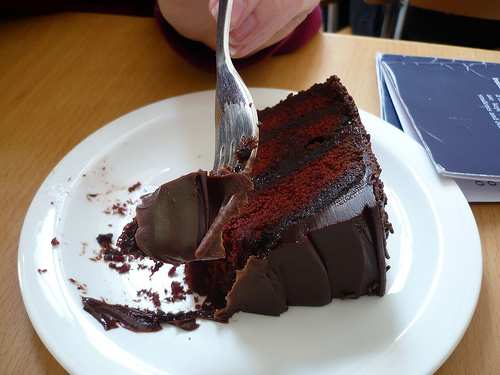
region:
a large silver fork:
[193, 3, 268, 190]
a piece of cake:
[104, 60, 416, 336]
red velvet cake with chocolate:
[93, 80, 410, 315]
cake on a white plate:
[18, 89, 487, 368]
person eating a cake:
[18, 5, 491, 372]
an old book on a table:
[366, 35, 498, 222]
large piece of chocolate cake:
[10, 7, 495, 373]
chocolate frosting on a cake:
[12, 60, 482, 365]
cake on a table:
[8, 9, 491, 370]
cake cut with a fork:
[21, 5, 494, 370]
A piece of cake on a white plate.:
[27, 81, 467, 373]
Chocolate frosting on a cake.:
[237, 209, 417, 341]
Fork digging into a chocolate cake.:
[166, 45, 303, 251]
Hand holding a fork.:
[136, 1, 286, 262]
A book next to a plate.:
[364, 46, 499, 213]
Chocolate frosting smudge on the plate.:
[65, 277, 208, 347]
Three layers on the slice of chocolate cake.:
[187, 73, 390, 313]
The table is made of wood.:
[13, 33, 498, 372]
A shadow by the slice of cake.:
[237, 278, 400, 360]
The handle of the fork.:
[198, 1, 245, 69]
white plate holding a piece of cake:
[35, 76, 442, 373]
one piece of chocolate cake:
[158, 78, 390, 304]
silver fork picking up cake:
[136, 66, 260, 273]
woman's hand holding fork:
[206, 2, 263, 172]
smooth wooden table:
[8, 20, 496, 360]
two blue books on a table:
[372, 49, 497, 209]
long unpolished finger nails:
[225, 11, 259, 63]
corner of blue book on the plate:
[404, 135, 475, 207]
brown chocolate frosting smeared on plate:
[74, 293, 197, 340]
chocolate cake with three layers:
[259, 75, 391, 299]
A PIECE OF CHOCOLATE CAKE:
[112, 126, 242, 268]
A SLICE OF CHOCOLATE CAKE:
[185, 70, 395, 320]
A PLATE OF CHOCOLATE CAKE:
[10, 75, 485, 365]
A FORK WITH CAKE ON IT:
[126, 2, 261, 273]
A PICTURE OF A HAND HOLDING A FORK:
[146, 0, 326, 186]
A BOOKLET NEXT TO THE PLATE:
[370, 45, 495, 210]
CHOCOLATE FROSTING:
[255, 242, 390, 312]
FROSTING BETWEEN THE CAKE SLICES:
[240, 120, 362, 190]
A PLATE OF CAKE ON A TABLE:
[9, 58, 494, 368]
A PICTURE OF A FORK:
[187, 13, 262, 183]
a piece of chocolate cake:
[141, 74, 392, 324]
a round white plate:
[16, 83, 481, 371]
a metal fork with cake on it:
[195, 0, 261, 257]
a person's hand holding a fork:
[156, 0, 318, 60]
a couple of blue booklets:
[375, 50, 499, 204]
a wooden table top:
[0, 5, 498, 373]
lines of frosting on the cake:
[254, 101, 369, 251]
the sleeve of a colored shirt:
[153, 3, 320, 73]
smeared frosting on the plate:
[82, 176, 204, 340]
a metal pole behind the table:
[371, 0, 413, 40]